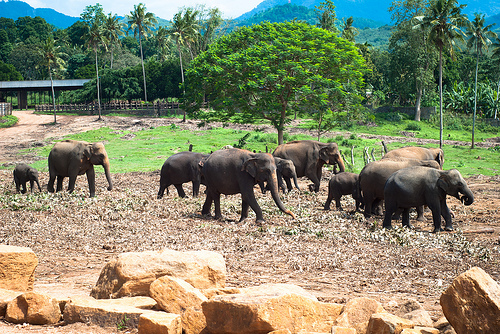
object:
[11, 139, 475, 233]
herd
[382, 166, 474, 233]
elephant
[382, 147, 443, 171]
elephant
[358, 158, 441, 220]
elephant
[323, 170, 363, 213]
elephant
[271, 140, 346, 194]
elephant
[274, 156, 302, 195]
elephant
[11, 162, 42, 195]
elephant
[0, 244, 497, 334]
elephant enclosure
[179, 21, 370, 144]
leaves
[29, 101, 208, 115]
fence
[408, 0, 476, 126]
palm tree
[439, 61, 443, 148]
trunk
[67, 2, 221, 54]
leaves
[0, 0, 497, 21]
mountains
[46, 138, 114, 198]
elephant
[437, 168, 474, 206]
elephant head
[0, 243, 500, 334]
rock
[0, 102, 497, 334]
preserve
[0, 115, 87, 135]
dirt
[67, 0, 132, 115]
palm trees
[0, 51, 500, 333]
elephants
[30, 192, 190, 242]
grass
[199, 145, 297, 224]
elephant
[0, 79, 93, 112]
building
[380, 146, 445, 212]
elephant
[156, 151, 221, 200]
elephant